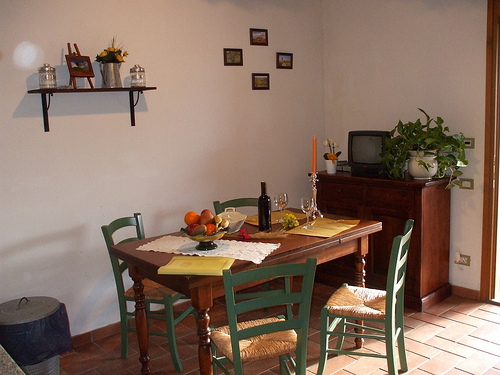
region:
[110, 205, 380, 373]
A wooden table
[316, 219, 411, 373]
A green and brown chair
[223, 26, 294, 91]
A photo display on the wall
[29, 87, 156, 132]
A hanging shelf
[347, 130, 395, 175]
A small boxy television set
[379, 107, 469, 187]
A green plant in a white vase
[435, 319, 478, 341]
A floor tile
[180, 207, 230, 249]
A bowl of fruit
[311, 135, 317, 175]
An orange candle stick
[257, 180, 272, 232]
A bottle of wine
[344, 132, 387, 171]
a small black t.v.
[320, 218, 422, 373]
a green dining chair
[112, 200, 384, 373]
a brown wooden table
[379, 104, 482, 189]
a green potted plant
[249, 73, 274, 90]
a small picture frame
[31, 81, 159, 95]
a long shelf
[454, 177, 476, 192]
a light switch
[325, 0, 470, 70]
part of a white wall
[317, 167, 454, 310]
a large brown cabinet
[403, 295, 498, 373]
part of a brick floor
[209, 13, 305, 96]
The pictures are on the wall.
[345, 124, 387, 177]
The TV is black.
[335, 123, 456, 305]
The TV is on the table.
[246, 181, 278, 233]
The bottle is on the table.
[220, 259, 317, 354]
The chair is green.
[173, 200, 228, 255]
The fruit is in the bowl.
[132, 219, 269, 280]
The placemat is white.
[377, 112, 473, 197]
The plant is on the table.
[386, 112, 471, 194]
The plant is in the white pot.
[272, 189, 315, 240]
Two wine glasses on the table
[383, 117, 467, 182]
Potted plant on the side table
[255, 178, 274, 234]
Bottle of wine on the table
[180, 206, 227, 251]
Fruit in a bowl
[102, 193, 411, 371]
Four chairs at the table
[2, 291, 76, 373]
Trash can in the corner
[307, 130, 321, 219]
Orange candle in holder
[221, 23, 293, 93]
Four small pictures on the wall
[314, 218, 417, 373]
Green chair with wicker seat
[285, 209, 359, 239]
Yellow placemat on the table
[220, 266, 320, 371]
green dining chair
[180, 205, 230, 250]
bowl of fruit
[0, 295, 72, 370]
tin trash can with black bag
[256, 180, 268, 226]
black glass wine bottle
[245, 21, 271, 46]
picture frame on wall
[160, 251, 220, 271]
yellow placemat on table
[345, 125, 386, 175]
small black tv on top table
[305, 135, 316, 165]
orange candlestick in candleholder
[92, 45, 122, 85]
yellow flowers in tin can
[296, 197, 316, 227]
wine glass sitting on table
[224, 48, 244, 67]
picture is on the wall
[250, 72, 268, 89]
picture is on the wall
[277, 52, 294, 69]
picture is on the wall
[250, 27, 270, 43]
picture is on the wall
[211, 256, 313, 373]
wood chair is green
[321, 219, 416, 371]
wood chair is green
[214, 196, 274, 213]
wood chair is green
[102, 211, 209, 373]
wood chair is green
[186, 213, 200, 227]
fruit is in a basket